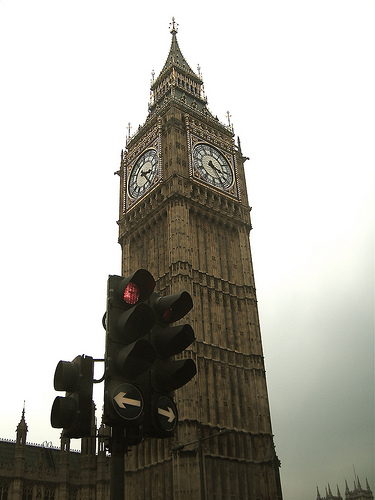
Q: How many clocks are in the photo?
A: Two.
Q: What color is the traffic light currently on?
A: Red.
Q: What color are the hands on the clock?
A: Black.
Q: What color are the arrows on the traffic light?
A: White.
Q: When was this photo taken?
A: Daytime.